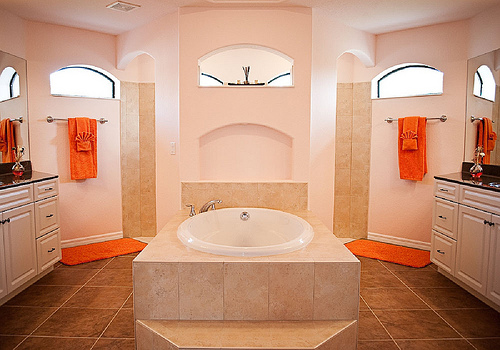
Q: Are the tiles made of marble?
A: Yes, the tiles are made of marble.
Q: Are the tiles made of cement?
A: No, the tiles are made of marble.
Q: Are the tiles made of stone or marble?
A: The tiles are made of marble.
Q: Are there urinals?
A: No, there are no urinals.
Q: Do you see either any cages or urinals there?
A: No, there are no urinals or cages.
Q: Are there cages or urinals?
A: No, there are no urinals or cages.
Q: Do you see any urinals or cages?
A: No, there are no urinals or cages.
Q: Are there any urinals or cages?
A: No, there are no urinals or cages.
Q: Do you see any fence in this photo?
A: No, there are no fences.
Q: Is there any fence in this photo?
A: No, there are no fences.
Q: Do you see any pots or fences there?
A: No, there are no fences or pots.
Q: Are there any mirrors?
A: Yes, there is a mirror.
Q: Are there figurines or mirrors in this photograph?
A: Yes, there is a mirror.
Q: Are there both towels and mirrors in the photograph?
A: Yes, there are both a mirror and a towel.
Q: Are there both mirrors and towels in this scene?
A: Yes, there are both a mirror and a towel.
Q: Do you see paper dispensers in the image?
A: No, there are no paper dispensers.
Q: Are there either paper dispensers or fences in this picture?
A: No, there are no paper dispensers or fences.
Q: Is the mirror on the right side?
A: Yes, the mirror is on the right of the image.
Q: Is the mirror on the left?
A: No, the mirror is on the right of the image.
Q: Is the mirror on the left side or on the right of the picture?
A: The mirror is on the right of the image.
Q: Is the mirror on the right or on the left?
A: The mirror is on the right of the image.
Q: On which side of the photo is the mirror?
A: The mirror is on the right of the image.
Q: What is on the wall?
A: The mirror is on the wall.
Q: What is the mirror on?
A: The mirror is on the wall.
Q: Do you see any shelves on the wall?
A: No, there is a mirror on the wall.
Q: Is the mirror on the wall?
A: Yes, the mirror is on the wall.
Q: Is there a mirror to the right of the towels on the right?
A: Yes, there is a mirror to the right of the towels.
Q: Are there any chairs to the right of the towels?
A: No, there is a mirror to the right of the towels.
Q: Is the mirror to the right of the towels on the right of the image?
A: Yes, the mirror is to the right of the towels.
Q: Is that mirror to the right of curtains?
A: No, the mirror is to the right of the towels.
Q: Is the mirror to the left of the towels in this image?
A: No, the mirror is to the right of the towels.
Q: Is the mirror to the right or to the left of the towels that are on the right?
A: The mirror is to the right of the towels.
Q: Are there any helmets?
A: No, there are no helmets.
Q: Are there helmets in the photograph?
A: No, there are no helmets.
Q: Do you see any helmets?
A: No, there are no helmets.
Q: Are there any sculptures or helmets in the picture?
A: No, there are no helmets or sculptures.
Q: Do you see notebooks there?
A: No, there are no notebooks.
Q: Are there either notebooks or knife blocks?
A: No, there are no notebooks or knife blocks.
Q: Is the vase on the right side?
A: Yes, the vase is on the right of the image.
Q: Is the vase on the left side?
A: No, the vase is on the right of the image.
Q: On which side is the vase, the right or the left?
A: The vase is on the right of the image.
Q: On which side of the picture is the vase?
A: The vase is on the right of the image.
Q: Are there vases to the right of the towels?
A: Yes, there is a vase to the right of the towels.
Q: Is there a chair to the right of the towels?
A: No, there is a vase to the right of the towels.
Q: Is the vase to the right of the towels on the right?
A: Yes, the vase is to the right of the towels.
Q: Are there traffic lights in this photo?
A: No, there are no traffic lights.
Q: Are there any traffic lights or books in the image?
A: No, there are no traffic lights or books.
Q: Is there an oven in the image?
A: No, there are no ovens.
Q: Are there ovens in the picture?
A: No, there are no ovens.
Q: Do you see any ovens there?
A: No, there are no ovens.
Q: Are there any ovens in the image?
A: No, there are no ovens.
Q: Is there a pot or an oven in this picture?
A: No, there are no ovens or pots.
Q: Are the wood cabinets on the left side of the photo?
A: No, the cabinets are on the right of the image.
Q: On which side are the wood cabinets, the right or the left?
A: The cabinets are on the right of the image.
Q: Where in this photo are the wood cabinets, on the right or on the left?
A: The cabinets are on the right of the image.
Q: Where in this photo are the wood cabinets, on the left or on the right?
A: The cabinets are on the right of the image.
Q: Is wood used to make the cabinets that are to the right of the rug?
A: Yes, the cabinets are made of wood.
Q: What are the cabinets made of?
A: The cabinets are made of wood.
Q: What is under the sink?
A: The cabinets are under the sink.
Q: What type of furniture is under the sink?
A: The pieces of furniture are cabinets.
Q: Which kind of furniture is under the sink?
A: The pieces of furniture are cabinets.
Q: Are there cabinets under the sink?
A: Yes, there are cabinets under the sink.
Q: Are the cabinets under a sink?
A: Yes, the cabinets are under a sink.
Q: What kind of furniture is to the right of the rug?
A: The pieces of furniture are cabinets.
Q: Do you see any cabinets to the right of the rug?
A: Yes, there are cabinets to the right of the rug.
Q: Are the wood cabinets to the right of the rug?
A: Yes, the cabinets are to the right of the rug.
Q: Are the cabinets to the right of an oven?
A: No, the cabinets are to the right of the rug.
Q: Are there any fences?
A: No, there are no fences.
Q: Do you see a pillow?
A: No, there are no pillows.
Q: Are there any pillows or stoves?
A: No, there are no pillows or stoves.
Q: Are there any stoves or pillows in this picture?
A: No, there are no pillows or stoves.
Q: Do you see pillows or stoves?
A: No, there are no pillows or stoves.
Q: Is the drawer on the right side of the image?
A: Yes, the drawer is on the right of the image.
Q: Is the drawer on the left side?
A: No, the drawer is on the right of the image.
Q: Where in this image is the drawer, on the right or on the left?
A: The drawer is on the right of the image.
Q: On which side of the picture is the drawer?
A: The drawer is on the right of the image.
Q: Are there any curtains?
A: No, there are no curtains.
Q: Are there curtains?
A: No, there are no curtains.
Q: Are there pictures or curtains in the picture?
A: No, there are no curtains or pictures.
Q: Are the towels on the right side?
A: Yes, the towels are on the right of the image.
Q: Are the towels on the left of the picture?
A: No, the towels are on the right of the image.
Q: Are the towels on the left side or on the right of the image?
A: The towels are on the right of the image.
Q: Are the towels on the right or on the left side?
A: The towels are on the right of the image.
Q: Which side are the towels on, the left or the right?
A: The towels are on the right of the image.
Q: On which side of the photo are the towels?
A: The towels are on the right of the image.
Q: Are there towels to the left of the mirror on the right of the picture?
A: Yes, there are towels to the left of the mirror.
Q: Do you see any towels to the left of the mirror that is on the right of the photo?
A: Yes, there are towels to the left of the mirror.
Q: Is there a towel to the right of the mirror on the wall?
A: No, the towels are to the left of the mirror.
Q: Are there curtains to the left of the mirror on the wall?
A: No, there are towels to the left of the mirror.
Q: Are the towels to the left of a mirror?
A: Yes, the towels are to the left of a mirror.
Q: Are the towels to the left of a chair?
A: No, the towels are to the left of a mirror.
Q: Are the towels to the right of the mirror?
A: No, the towels are to the left of the mirror.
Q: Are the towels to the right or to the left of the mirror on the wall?
A: The towels are to the left of the mirror.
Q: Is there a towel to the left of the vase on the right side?
A: Yes, there are towels to the left of the vase.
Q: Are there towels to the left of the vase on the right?
A: Yes, there are towels to the left of the vase.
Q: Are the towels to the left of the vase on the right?
A: Yes, the towels are to the left of the vase.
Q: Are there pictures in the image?
A: No, there are no pictures.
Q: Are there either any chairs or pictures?
A: No, there are no pictures or chairs.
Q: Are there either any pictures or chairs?
A: No, there are no pictures or chairs.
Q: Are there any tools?
A: No, there are no tools.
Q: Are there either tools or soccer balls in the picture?
A: No, there are no tools or soccer balls.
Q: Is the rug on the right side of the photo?
A: Yes, the rug is on the right of the image.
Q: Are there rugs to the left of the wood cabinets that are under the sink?
A: Yes, there is a rug to the left of the cabinets.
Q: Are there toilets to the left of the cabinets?
A: No, there is a rug to the left of the cabinets.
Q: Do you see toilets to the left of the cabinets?
A: No, there is a rug to the left of the cabinets.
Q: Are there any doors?
A: Yes, there are doors.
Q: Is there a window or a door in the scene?
A: Yes, there are doors.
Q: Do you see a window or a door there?
A: Yes, there are doors.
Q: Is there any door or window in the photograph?
A: Yes, there are doors.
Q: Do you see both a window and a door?
A: Yes, there are both a door and a window.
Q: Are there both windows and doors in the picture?
A: Yes, there are both doors and a window.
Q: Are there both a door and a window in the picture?
A: Yes, there are both a door and a window.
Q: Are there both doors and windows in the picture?
A: Yes, there are both doors and a window.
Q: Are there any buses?
A: No, there are no buses.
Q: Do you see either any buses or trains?
A: No, there are no buses or trains.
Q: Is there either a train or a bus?
A: No, there are no buses or trains.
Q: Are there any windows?
A: Yes, there is a window.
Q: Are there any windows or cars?
A: Yes, there is a window.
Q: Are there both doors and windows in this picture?
A: Yes, there are both a window and doors.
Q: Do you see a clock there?
A: No, there are no clocks.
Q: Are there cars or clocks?
A: No, there are no clocks or cars.